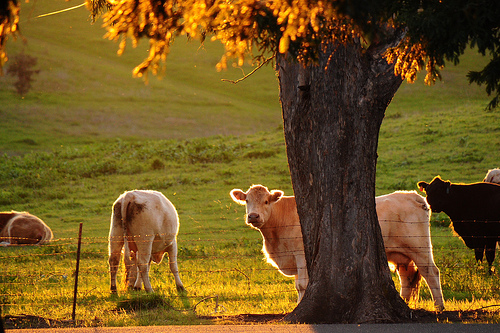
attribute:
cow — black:
[402, 169, 497, 273]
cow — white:
[100, 175, 188, 298]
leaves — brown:
[83, 0, 444, 85]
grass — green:
[382, 114, 497, 182]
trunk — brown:
[283, 37, 438, 306]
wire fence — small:
[5, 225, 498, 331]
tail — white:
[113, 196, 152, 291]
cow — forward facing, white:
[228, 184, 445, 312]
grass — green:
[50, 102, 281, 174]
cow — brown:
[2, 205, 69, 249]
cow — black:
[417, 177, 499, 267]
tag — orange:
[418, 183, 425, 188]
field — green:
[0, 2, 495, 324]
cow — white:
[106, 186, 184, 293]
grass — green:
[41, 107, 136, 187]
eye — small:
[258, 192, 272, 206]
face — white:
[243, 191, 272, 226]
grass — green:
[0, 1, 498, 331]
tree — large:
[82, 0, 497, 330]